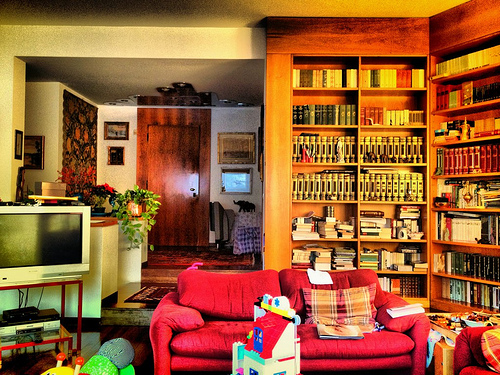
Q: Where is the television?
A: To the left of a red couch.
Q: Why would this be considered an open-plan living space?
A: Because there is no wall separating the front hall from the living room.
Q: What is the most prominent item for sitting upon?
A: A red sofa.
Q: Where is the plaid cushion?
A: On the red sofa.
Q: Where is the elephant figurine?
A: In the front hallway, on a purple, polks-dot table cloth.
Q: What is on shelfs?
A: Books.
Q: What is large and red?
A: Couch.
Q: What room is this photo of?
A: Livingroom.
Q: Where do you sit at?
A: The sofa.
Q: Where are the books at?
A: Book shelves.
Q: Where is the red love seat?
A: Living room.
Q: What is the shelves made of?
A: Wood.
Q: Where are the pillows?
A: On the couch.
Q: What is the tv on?
A: A stand.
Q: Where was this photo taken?
A: In a living room.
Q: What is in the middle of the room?
A: A couch.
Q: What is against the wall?
A: Shelves.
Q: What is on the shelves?
A: Books.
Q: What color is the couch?
A: The couch is red.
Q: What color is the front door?
A: The front door is brown.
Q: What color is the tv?
A: The tv is silver.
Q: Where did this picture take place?
A: It took place in the living room.